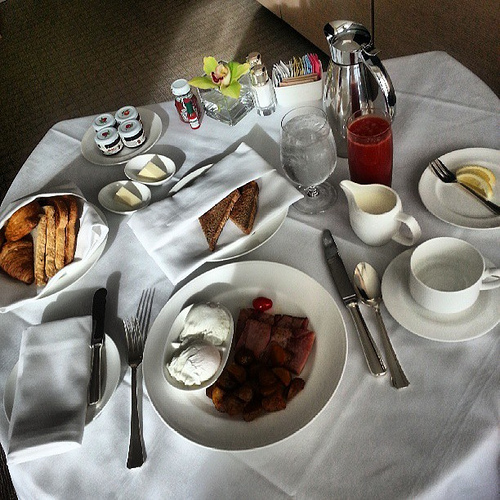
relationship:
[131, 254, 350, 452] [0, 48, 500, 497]
plate on top of table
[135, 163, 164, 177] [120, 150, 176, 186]
butter on plate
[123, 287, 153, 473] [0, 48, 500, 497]
fork on table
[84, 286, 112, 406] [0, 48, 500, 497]
knife on table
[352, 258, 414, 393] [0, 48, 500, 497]
spoon on table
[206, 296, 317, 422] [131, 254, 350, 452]
food on plate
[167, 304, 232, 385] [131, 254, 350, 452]
eggs on plate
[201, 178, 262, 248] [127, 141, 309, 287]
toast in napkin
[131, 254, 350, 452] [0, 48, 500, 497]
plate on table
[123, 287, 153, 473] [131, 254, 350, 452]
fork near plate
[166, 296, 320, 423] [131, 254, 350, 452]
food on plate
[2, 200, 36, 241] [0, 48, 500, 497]
bread on table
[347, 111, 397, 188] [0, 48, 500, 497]
glass on table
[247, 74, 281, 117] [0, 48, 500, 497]
shaker on table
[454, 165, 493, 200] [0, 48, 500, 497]
lemon slice on table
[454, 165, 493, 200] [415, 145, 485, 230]
lemon slice lying on top of plate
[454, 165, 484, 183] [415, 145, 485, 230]
lemon slice lying on top of plate